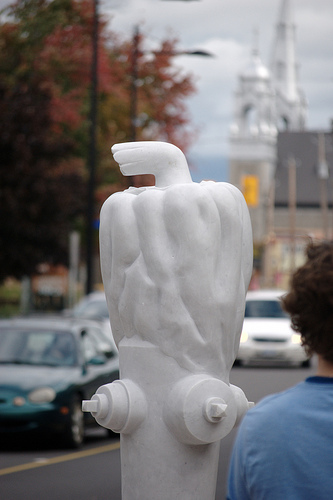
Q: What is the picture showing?
A: It is showing a street.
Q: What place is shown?
A: It is a street.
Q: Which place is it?
A: It is a street.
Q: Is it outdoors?
A: Yes, it is outdoors.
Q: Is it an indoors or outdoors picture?
A: It is outdoors.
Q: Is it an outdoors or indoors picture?
A: It is outdoors.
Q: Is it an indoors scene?
A: No, it is outdoors.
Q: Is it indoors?
A: No, it is outdoors.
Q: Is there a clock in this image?
A: No, there are no clocks.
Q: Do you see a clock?
A: No, there are no clocks.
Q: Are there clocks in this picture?
A: No, there are no clocks.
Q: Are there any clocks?
A: No, there are no clocks.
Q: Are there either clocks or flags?
A: No, there are no clocks or flags.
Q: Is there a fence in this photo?
A: No, there are no fences.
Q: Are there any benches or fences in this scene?
A: No, there are no fences or benches.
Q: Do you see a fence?
A: No, there are no fences.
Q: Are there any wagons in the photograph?
A: No, there are no wagons.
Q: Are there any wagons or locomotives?
A: No, there are no wagons or locomotives.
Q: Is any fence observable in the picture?
A: No, there are no fences.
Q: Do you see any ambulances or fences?
A: No, there are no fences or ambulances.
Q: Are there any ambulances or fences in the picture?
A: No, there are no fences or ambulances.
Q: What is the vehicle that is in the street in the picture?
A: The vehicle is a car.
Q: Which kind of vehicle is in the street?
A: The vehicle is a car.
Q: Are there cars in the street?
A: Yes, there is a car in the street.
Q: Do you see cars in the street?
A: Yes, there is a car in the street.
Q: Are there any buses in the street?
A: No, there is a car in the street.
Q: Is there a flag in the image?
A: No, there are no flags.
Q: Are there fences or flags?
A: No, there are no flags or fences.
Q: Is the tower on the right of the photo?
A: Yes, the tower is on the right of the image.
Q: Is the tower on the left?
A: No, the tower is on the right of the image.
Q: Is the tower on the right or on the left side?
A: The tower is on the right of the image.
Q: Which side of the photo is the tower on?
A: The tower is on the right of the image.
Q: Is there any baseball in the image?
A: No, there are no baseballs.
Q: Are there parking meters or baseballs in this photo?
A: No, there are no baseballs or parking meters.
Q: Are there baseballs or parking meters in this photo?
A: No, there are no baseballs or parking meters.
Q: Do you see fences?
A: No, there are no fences.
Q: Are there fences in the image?
A: No, there are no fences.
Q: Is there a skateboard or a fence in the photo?
A: No, there are no fences or skateboards.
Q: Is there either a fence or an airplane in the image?
A: No, there are no fences or airplanes.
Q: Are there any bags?
A: No, there are no bags.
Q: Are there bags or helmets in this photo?
A: No, there are no bags or helmets.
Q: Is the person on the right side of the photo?
A: Yes, the person is on the right of the image.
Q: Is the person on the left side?
A: No, the person is on the right of the image.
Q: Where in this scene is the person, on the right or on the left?
A: The person is on the right of the image.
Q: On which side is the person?
A: The person is on the right of the image.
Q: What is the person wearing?
A: The person is wearing a tee shirt.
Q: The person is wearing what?
A: The person is wearing a tee shirt.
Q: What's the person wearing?
A: The person is wearing a tee shirt.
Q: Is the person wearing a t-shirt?
A: Yes, the person is wearing a t-shirt.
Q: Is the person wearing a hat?
A: No, the person is wearing a t-shirt.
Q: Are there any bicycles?
A: No, there are no bicycles.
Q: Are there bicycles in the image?
A: No, there are no bicycles.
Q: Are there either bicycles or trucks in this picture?
A: No, there are no bicycles or trucks.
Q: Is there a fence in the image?
A: No, there are no fences.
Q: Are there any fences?
A: No, there are no fences.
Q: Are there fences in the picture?
A: No, there are no fences.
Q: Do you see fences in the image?
A: No, there are no fences.